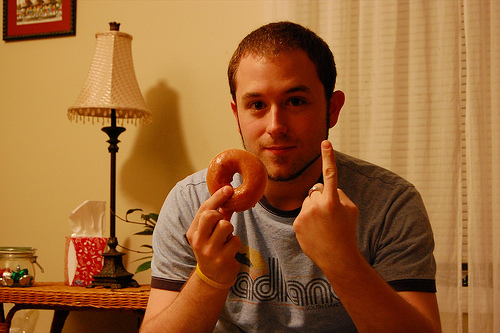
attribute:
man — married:
[139, 22, 443, 332]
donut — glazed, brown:
[205, 150, 267, 212]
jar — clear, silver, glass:
[1, 244, 45, 287]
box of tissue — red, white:
[73, 236, 106, 285]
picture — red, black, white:
[2, 1, 76, 43]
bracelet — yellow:
[194, 263, 236, 292]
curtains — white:
[292, 2, 500, 330]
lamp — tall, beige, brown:
[69, 20, 140, 290]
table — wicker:
[1, 282, 152, 329]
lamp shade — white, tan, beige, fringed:
[69, 31, 148, 121]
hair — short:
[228, 22, 337, 101]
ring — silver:
[309, 185, 323, 196]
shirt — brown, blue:
[149, 151, 438, 332]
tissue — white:
[71, 198, 104, 237]